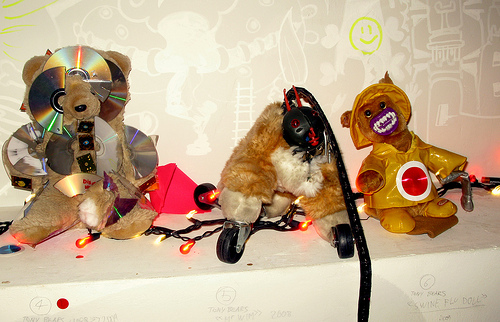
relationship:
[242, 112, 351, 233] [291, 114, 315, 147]
stuffed animal has mask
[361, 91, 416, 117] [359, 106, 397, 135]
hat on top of head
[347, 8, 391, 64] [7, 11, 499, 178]
happy face on wall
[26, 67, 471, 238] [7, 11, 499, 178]
toys in front of wall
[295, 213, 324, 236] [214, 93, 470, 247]
light next to animals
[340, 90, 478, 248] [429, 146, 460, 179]
animal has left arm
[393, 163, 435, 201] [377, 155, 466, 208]
circle attached to raincoat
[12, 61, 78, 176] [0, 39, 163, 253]
cds on toys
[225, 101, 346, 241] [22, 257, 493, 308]
plushie sitting on shelf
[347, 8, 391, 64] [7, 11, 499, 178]
happy face posted on wall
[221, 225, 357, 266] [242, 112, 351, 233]
wheels attached to stuffed animal